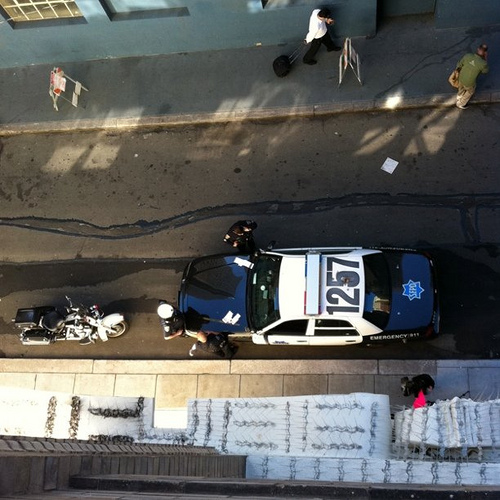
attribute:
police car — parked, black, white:
[175, 238, 442, 346]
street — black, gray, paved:
[0, 102, 499, 361]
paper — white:
[380, 157, 398, 176]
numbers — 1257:
[326, 255, 362, 313]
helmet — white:
[157, 303, 175, 320]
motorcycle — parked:
[12, 293, 128, 346]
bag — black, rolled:
[273, 54, 292, 76]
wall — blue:
[0, 0, 498, 69]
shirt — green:
[455, 51, 491, 85]